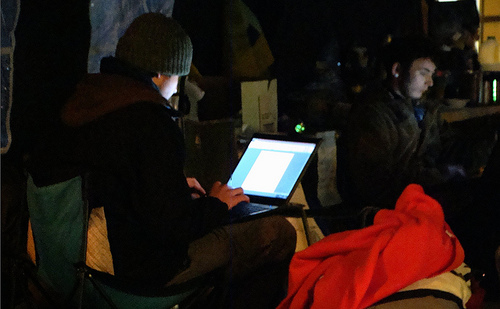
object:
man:
[23, 12, 297, 309]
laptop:
[222, 132, 324, 225]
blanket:
[271, 182, 465, 308]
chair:
[23, 168, 222, 308]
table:
[441, 104, 499, 129]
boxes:
[463, 71, 499, 108]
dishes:
[445, 97, 471, 109]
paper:
[315, 131, 344, 207]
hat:
[114, 12, 193, 76]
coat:
[27, 56, 230, 288]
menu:
[239, 79, 279, 135]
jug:
[477, 35, 500, 73]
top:
[486, 35, 495, 40]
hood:
[60, 71, 168, 128]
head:
[114, 12, 192, 102]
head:
[384, 36, 441, 101]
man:
[336, 37, 499, 290]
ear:
[390, 62, 402, 79]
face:
[161, 74, 179, 101]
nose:
[423, 78, 432, 87]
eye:
[419, 72, 427, 76]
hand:
[208, 180, 250, 210]